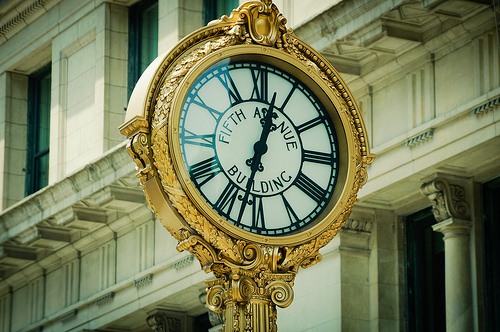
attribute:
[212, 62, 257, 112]
numeral — roman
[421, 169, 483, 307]
pillars — ornate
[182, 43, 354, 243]
clock — very ornate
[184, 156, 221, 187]
roman numeral — black 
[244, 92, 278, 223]
clock hand — black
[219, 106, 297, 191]
writing — black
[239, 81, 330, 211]
hand — black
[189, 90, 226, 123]
numeral — black 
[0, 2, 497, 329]
building — white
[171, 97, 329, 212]
clock — black 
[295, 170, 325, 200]
roman numeral — black, small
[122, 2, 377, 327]
clock — gold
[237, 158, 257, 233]
hand — black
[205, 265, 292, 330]
pole — golden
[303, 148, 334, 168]
roman numeral — small, black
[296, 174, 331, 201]
numeral — roman, small, black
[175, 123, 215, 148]
numeral — black 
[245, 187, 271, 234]
numeral — small, black, roman